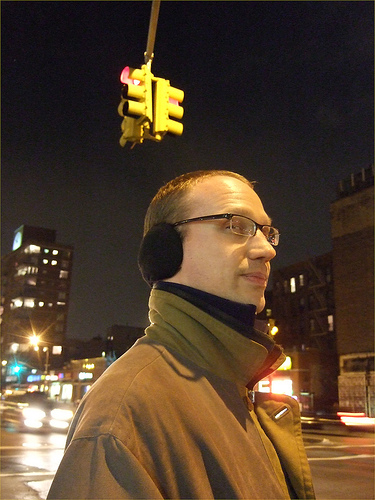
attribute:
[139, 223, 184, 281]
muff — black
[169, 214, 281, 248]
glasses — black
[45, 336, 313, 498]
jacket — brown